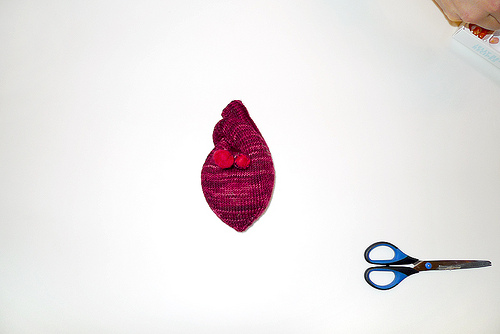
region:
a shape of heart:
[184, 76, 264, 237]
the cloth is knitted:
[197, 71, 270, 232]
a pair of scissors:
[338, 229, 498, 315]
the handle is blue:
[356, 230, 417, 310]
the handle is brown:
[356, 230, 421, 310]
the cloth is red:
[196, 95, 295, 262]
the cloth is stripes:
[181, 95, 293, 262]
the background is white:
[118, 27, 236, 287]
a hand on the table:
[441, 5, 498, 60]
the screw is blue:
[414, 234, 439, 279]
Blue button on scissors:
[421, 249, 436, 279]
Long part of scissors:
[438, 252, 495, 279]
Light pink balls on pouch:
[203, 146, 261, 171]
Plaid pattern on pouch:
[228, 111, 250, 141]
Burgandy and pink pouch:
[200, 100, 280, 250]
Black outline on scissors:
[359, 240, 399, 245]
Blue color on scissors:
[394, 247, 405, 261]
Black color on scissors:
[401, 256, 420, 265]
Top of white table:
[308, 67, 430, 168]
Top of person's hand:
[433, 2, 498, 32]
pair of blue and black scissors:
[362, 235, 495, 294]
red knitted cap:
[193, 89, 285, 236]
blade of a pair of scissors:
[418, 253, 495, 280]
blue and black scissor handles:
[358, 235, 422, 295]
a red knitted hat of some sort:
[195, 89, 289, 239]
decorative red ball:
[210, 141, 237, 172]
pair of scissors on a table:
[351, 236, 498, 293]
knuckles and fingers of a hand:
[432, 1, 499, 39]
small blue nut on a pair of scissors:
[422, 258, 433, 270]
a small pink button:
[482, 32, 498, 46]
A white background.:
[363, 90, 455, 175]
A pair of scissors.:
[350, 225, 495, 305]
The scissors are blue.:
[336, 228, 495, 305]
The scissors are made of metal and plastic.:
[346, 229, 498, 310]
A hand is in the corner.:
[416, 4, 497, 81]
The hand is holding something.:
[412, 2, 499, 74]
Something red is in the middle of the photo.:
[183, 88, 300, 246]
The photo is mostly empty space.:
[4, 1, 196, 319]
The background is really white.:
[318, 36, 423, 189]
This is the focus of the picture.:
[180, 79, 302, 261]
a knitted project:
[151, 68, 316, 264]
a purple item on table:
[153, 42, 299, 242]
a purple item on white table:
[127, 24, 332, 332]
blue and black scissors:
[332, 188, 499, 323]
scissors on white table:
[341, 195, 499, 313]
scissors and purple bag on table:
[142, 48, 497, 313]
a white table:
[257, 10, 492, 208]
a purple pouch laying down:
[132, 66, 442, 301]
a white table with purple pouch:
[101, 67, 306, 252]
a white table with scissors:
[308, 205, 464, 328]